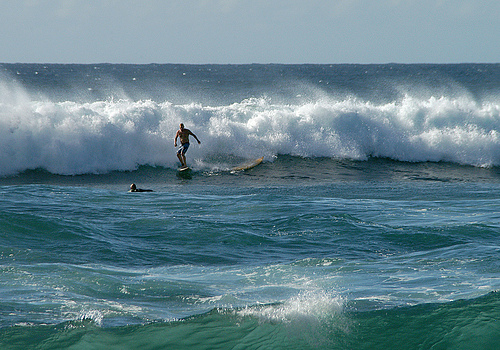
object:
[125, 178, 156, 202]
people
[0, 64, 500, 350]
water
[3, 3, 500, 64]
sky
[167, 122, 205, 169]
man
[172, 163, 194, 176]
board